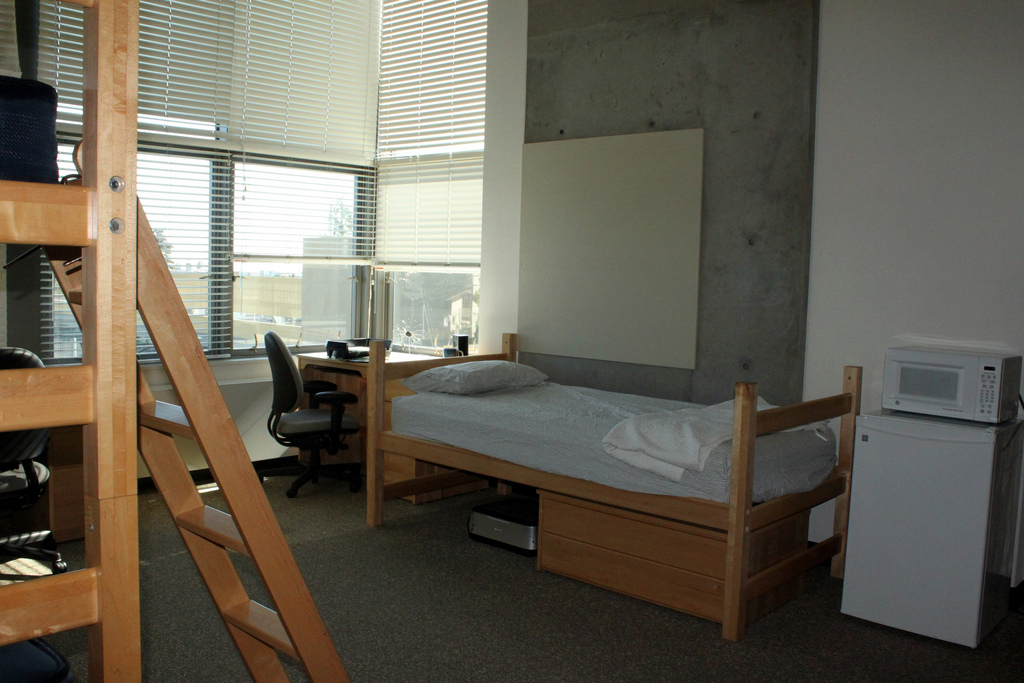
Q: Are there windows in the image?
A: Yes, there is a window.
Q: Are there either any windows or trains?
A: Yes, there is a window.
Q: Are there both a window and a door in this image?
A: No, there is a window but no doors.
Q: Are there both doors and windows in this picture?
A: No, there is a window but no doors.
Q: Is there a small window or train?
A: Yes, there is a small window.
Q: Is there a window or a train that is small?
A: Yes, the window is small.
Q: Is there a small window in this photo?
A: Yes, there is a small window.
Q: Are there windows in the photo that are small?
A: Yes, there is a window that is small.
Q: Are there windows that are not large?
A: Yes, there is a small window.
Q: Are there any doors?
A: No, there are no doors.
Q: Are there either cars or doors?
A: No, there are no doors or cars.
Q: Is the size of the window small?
A: Yes, the window is small.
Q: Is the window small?
A: Yes, the window is small.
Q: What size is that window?
A: The window is small.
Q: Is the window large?
A: No, the window is small.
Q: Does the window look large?
A: No, the window is small.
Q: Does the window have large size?
A: No, the window is small.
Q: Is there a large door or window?
A: No, there is a window but it is small.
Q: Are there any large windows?
A: No, there is a window but it is small.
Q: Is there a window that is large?
A: No, there is a window but it is small.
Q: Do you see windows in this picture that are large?
A: No, there is a window but it is small.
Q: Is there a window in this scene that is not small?
A: No, there is a window but it is small.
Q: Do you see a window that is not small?
A: No, there is a window but it is small.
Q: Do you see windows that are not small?
A: No, there is a window but it is small.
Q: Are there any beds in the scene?
A: Yes, there is a bed.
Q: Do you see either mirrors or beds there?
A: Yes, there is a bed.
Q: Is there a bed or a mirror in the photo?
A: Yes, there is a bed.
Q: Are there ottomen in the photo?
A: No, there are no ottomen.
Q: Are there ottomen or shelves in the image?
A: No, there are no ottomen or shelves.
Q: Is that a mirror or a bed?
A: That is a bed.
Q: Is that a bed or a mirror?
A: That is a bed.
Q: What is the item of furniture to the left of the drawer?
A: The piece of furniture is a bed.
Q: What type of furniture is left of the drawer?
A: The piece of furniture is a bed.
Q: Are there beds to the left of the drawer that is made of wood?
A: Yes, there is a bed to the left of the drawer.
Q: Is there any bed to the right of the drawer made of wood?
A: No, the bed is to the left of the drawer.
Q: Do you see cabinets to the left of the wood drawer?
A: No, there is a bed to the left of the drawer.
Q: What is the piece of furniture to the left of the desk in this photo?
A: The piece of furniture is a bed.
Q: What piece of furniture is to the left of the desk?
A: The piece of furniture is a bed.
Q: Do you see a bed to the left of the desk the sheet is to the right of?
A: Yes, there is a bed to the left of the desk.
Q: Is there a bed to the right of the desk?
A: No, the bed is to the left of the desk.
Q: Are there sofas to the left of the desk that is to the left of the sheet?
A: No, there is a bed to the left of the desk.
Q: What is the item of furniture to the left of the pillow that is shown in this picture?
A: The piece of furniture is a bed.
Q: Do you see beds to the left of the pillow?
A: Yes, there is a bed to the left of the pillow.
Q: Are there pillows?
A: Yes, there is a pillow.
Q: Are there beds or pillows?
A: Yes, there is a pillow.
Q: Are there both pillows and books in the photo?
A: No, there is a pillow but no books.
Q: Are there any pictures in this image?
A: No, there are no pictures.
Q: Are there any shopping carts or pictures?
A: No, there are no pictures or shopping carts.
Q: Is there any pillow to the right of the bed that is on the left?
A: Yes, there is a pillow to the right of the bed.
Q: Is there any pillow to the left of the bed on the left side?
A: No, the pillow is to the right of the bed.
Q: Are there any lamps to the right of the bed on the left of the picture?
A: No, there is a pillow to the right of the bed.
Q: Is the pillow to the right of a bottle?
A: No, the pillow is to the right of a bed.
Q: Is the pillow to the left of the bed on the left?
A: No, the pillow is to the right of the bed.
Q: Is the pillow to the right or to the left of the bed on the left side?
A: The pillow is to the right of the bed.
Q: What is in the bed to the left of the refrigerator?
A: The pillow is in the bed.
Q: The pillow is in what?
A: The pillow is in the bed.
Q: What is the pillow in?
A: The pillow is in the bed.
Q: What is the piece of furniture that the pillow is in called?
A: The piece of furniture is a bed.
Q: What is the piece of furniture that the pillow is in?
A: The piece of furniture is a bed.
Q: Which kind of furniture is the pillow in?
A: The pillow is in the bed.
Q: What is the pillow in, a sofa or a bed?
A: The pillow is in a bed.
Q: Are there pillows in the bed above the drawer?
A: Yes, there is a pillow in the bed.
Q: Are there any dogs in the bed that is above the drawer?
A: No, there is a pillow in the bed.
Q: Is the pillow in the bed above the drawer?
A: Yes, the pillow is in the bed.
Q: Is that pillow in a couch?
A: No, the pillow is in the bed.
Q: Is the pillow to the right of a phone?
A: No, the pillow is to the right of an office chair.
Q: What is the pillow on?
A: The pillow is on the bed.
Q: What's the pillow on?
A: The pillow is on the bed.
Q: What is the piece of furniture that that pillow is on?
A: The piece of furniture is a bed.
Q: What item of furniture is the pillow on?
A: The pillow is on the bed.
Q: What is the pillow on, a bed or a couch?
A: The pillow is on a bed.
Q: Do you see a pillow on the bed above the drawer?
A: Yes, there is a pillow on the bed.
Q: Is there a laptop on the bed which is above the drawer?
A: No, there is a pillow on the bed.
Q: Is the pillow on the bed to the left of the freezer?
A: Yes, the pillow is on the bed.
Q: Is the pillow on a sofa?
A: No, the pillow is on the bed.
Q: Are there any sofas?
A: No, there are no sofas.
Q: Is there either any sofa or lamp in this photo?
A: No, there are no sofas or lamps.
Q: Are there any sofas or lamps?
A: No, there are no sofas or lamps.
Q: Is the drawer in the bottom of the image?
A: Yes, the drawer is in the bottom of the image.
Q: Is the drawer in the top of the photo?
A: No, the drawer is in the bottom of the image.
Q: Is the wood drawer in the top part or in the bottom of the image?
A: The drawer is in the bottom of the image.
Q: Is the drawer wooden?
A: Yes, the drawer is wooden.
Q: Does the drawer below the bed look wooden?
A: Yes, the drawer is wooden.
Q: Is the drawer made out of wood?
A: Yes, the drawer is made of wood.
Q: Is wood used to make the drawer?
A: Yes, the drawer is made of wood.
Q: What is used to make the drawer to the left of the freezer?
A: The drawer is made of wood.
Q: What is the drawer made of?
A: The drawer is made of wood.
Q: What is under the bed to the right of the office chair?
A: The drawer is under the bed.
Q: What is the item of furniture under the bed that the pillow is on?
A: The piece of furniture is a drawer.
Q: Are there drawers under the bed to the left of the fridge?
A: Yes, there is a drawer under the bed.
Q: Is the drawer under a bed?
A: Yes, the drawer is under a bed.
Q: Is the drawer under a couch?
A: No, the drawer is under a bed.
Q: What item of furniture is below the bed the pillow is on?
A: The piece of furniture is a drawer.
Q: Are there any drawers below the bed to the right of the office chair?
A: Yes, there is a drawer below the bed.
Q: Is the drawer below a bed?
A: Yes, the drawer is below a bed.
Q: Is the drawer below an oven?
A: No, the drawer is below a bed.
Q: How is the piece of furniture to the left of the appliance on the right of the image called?
A: The piece of furniture is a drawer.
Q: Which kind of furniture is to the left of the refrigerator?
A: The piece of furniture is a drawer.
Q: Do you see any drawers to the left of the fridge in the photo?
A: Yes, there is a drawer to the left of the fridge.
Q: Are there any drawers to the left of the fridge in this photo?
A: Yes, there is a drawer to the left of the fridge.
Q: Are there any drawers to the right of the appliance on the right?
A: No, the drawer is to the left of the refrigerator.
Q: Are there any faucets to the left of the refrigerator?
A: No, there is a drawer to the left of the refrigerator.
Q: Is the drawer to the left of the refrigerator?
A: Yes, the drawer is to the left of the refrigerator.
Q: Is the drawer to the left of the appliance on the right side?
A: Yes, the drawer is to the left of the refrigerator.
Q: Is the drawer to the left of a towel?
A: No, the drawer is to the left of the refrigerator.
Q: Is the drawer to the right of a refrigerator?
A: No, the drawer is to the left of a refrigerator.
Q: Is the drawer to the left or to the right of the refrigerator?
A: The drawer is to the left of the refrigerator.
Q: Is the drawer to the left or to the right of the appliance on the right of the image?
A: The drawer is to the left of the refrigerator.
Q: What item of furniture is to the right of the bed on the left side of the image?
A: The piece of furniture is a drawer.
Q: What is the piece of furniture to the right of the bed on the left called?
A: The piece of furniture is a drawer.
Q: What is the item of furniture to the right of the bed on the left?
A: The piece of furniture is a drawer.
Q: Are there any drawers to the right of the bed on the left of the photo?
A: Yes, there is a drawer to the right of the bed.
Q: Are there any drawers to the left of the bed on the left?
A: No, the drawer is to the right of the bed.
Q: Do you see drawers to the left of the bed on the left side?
A: No, the drawer is to the right of the bed.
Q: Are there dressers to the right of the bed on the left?
A: No, there is a drawer to the right of the bed.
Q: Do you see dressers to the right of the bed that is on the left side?
A: No, there is a drawer to the right of the bed.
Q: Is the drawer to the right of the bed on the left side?
A: Yes, the drawer is to the right of the bed.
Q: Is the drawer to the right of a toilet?
A: No, the drawer is to the right of the bed.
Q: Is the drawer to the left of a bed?
A: No, the drawer is to the right of a bed.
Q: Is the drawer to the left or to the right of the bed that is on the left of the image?
A: The drawer is to the right of the bed.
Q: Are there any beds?
A: Yes, there is a bed.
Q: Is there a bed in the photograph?
A: Yes, there is a bed.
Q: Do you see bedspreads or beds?
A: Yes, there is a bed.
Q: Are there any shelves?
A: No, there are no shelves.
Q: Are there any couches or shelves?
A: No, there are no shelves or couches.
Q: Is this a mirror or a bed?
A: This is a bed.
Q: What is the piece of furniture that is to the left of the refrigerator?
A: The piece of furniture is a bed.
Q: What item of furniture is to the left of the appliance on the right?
A: The piece of furniture is a bed.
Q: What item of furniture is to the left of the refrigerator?
A: The piece of furniture is a bed.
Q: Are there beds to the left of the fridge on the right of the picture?
A: Yes, there is a bed to the left of the refrigerator.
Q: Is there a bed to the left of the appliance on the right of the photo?
A: Yes, there is a bed to the left of the refrigerator.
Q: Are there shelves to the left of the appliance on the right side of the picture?
A: No, there is a bed to the left of the refrigerator.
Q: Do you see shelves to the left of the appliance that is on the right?
A: No, there is a bed to the left of the refrigerator.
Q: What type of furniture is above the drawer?
A: The piece of furniture is a bed.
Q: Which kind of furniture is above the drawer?
A: The piece of furniture is a bed.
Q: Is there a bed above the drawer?
A: Yes, there is a bed above the drawer.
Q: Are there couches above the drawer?
A: No, there is a bed above the drawer.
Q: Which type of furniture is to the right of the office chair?
A: The piece of furniture is a bed.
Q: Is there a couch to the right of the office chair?
A: No, there is a bed to the right of the office chair.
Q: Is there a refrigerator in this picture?
A: Yes, there is a refrigerator.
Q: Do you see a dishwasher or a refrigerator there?
A: Yes, there is a refrigerator.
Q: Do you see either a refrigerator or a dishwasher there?
A: Yes, there is a refrigerator.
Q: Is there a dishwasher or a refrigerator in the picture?
A: Yes, there is a refrigerator.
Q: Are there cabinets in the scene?
A: No, there are no cabinets.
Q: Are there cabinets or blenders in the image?
A: No, there are no cabinets or blenders.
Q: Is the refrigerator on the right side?
A: Yes, the refrigerator is on the right of the image.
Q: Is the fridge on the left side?
A: No, the fridge is on the right of the image.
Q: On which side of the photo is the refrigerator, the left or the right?
A: The refrigerator is on the right of the image.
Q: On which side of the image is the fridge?
A: The fridge is on the right of the image.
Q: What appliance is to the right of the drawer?
A: The appliance is a refrigerator.